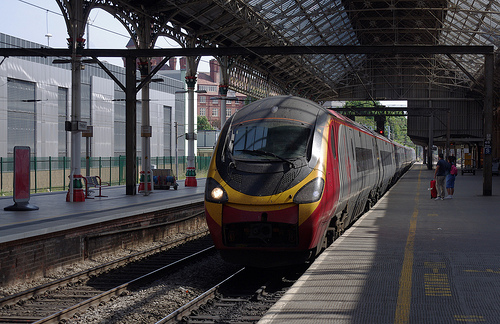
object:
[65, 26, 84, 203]
pole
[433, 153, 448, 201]
man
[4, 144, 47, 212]
sign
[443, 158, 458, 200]
people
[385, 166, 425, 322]
stripe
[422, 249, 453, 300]
words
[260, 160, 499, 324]
concrete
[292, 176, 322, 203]
light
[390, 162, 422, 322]
stripe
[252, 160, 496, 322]
side walk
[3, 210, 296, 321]
tracks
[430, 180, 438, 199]
bag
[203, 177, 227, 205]
headlight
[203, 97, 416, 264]
train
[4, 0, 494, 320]
train stop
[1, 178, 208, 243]
platform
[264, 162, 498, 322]
sidewalk